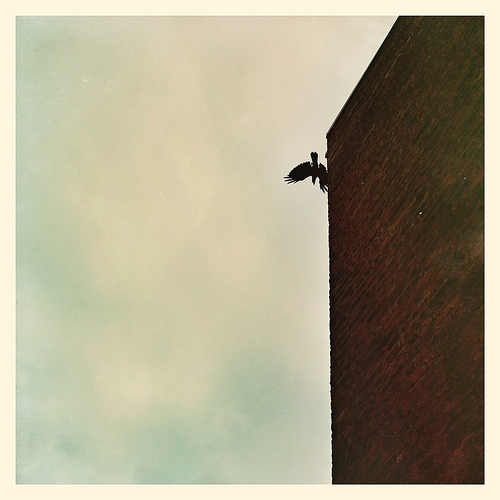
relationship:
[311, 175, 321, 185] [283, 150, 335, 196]
tail of bird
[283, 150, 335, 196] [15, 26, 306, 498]
bird in sky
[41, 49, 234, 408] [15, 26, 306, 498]
clouds in sky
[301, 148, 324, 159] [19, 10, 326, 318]
head in sky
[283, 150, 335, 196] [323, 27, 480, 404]
bird flying next to building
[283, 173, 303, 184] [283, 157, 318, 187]
feathers on wing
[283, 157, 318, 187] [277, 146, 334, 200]
wing of bird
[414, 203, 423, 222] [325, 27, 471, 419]
spot on side of building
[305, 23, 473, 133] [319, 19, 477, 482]
rooftop of building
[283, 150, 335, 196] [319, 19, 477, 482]
bird flying close to building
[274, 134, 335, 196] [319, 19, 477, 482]
bird flying next to a building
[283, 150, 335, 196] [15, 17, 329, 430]
bird flying in sky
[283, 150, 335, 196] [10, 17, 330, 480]
bird falling from sky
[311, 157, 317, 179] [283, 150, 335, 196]
underside of a bird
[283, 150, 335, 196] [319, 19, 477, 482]
bird flying near building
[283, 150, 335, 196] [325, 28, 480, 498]
bird flying near building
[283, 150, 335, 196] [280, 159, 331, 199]
bird flapping its wings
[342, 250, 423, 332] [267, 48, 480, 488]
brick on building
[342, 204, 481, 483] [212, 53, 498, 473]
brick on building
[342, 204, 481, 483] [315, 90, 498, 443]
brick on building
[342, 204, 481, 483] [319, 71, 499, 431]
brick on building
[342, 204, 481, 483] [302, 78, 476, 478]
brick on building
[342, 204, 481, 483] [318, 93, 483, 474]
brick on building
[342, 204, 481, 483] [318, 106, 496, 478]
brick on building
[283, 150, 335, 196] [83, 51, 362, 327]
bird in sky